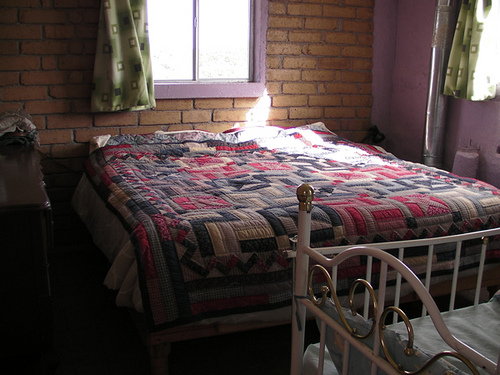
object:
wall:
[273, 9, 367, 136]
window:
[150, 0, 256, 84]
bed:
[69, 122, 500, 375]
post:
[289, 185, 314, 373]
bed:
[288, 180, 500, 375]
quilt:
[80, 126, 500, 333]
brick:
[295, 26, 360, 81]